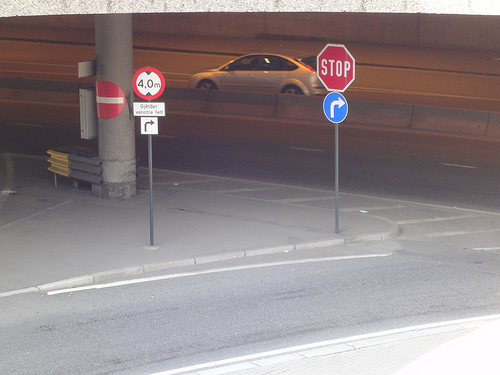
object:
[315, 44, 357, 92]
sign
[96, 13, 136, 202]
pillar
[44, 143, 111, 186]
barricade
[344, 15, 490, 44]
wall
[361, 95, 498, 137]
overpass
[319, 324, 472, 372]
sidewalk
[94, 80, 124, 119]
sign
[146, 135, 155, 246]
pole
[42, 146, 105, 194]
divider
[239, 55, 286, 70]
glass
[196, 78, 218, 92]
tire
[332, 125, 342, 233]
pole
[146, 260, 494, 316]
street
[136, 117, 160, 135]
sign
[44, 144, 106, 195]
barrier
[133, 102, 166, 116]
sign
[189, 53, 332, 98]
car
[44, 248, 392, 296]
lines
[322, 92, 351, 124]
sign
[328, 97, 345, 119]
arrows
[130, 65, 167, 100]
sign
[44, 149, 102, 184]
rail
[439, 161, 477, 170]
line